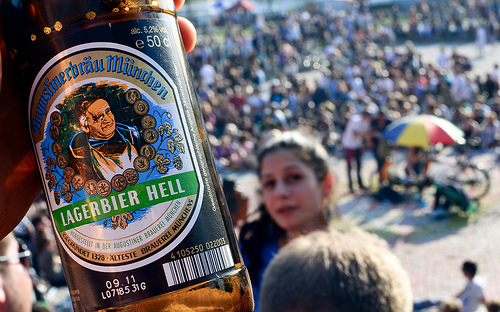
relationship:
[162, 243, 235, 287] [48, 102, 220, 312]
barcode on label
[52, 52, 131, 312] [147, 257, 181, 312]
close up of beer bottle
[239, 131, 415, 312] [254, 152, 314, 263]
girl looking at camera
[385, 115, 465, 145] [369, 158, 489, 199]
umbrella on bicycle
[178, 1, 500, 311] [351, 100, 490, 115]
crowd standing to right of crowd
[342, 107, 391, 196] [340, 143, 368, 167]
man standing in shorts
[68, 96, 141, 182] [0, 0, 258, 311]
male on beer bottle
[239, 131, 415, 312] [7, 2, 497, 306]
girl at camera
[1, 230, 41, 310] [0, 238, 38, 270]
man wearing glasses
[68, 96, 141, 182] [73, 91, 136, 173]
male of man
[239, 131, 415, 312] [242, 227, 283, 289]
girl in shirt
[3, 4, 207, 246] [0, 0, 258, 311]
hand holding beer bottle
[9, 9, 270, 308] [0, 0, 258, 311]
label on beer bottle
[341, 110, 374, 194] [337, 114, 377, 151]
man wearing shirt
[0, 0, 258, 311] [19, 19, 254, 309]
beer bottle with label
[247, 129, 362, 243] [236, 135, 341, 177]
girl with hair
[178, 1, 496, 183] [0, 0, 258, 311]
crowd behind beer bottle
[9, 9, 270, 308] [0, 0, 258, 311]
label glued to beer bottle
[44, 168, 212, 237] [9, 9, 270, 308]
stripe printed across label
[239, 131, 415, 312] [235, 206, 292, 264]
girl has hair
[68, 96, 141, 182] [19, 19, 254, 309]
male on label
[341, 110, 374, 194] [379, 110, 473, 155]
man near umbrella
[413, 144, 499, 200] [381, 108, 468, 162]
bicycle behind umbrella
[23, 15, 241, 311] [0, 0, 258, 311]
label on beer bottle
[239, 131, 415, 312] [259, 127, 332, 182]
girl has hair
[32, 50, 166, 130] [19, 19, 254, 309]
writing on label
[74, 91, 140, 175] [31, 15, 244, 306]
male on label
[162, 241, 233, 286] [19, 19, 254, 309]
barcode on label